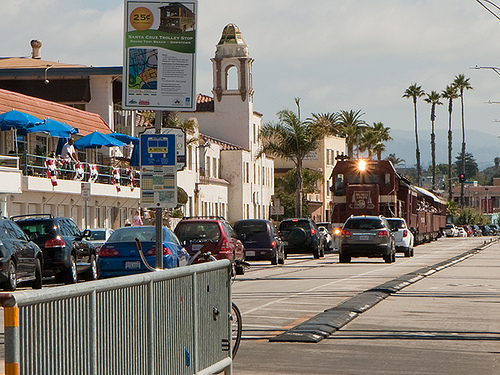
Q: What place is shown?
A: It is a road.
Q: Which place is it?
A: It is a road.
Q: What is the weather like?
A: It is cloudy.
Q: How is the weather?
A: It is cloudy.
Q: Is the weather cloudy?
A: Yes, it is cloudy.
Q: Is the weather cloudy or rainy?
A: It is cloudy.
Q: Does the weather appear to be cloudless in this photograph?
A: No, it is cloudy.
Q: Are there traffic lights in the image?
A: Yes, there is a traffic light.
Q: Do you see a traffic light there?
A: Yes, there is a traffic light.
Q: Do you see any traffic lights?
A: Yes, there is a traffic light.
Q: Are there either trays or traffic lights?
A: Yes, there is a traffic light.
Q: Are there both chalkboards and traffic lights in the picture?
A: No, there is a traffic light but no chalkboards.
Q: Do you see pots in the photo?
A: No, there are no pots.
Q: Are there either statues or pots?
A: No, there are no pots or statues.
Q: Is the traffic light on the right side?
A: Yes, the traffic light is on the right of the image.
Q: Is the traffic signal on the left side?
A: No, the traffic signal is on the right of the image.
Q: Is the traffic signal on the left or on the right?
A: The traffic signal is on the right of the image.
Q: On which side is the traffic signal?
A: The traffic signal is on the right of the image.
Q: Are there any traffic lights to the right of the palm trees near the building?
A: Yes, there is a traffic light to the right of the palm trees.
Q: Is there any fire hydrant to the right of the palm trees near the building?
A: No, there is a traffic light to the right of the palm trees.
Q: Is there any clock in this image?
A: No, there are no clocks.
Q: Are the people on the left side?
A: Yes, the people are on the left of the image.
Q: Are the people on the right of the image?
A: No, the people are on the left of the image.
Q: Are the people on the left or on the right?
A: The people are on the left of the image.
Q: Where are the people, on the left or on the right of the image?
A: The people are on the left of the image.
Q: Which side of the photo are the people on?
A: The people are on the left of the image.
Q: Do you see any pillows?
A: No, there are no pillows.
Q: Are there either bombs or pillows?
A: No, there are no pillows or bombs.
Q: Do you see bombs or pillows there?
A: No, there are no pillows or bombs.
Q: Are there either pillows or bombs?
A: No, there are no pillows or bombs.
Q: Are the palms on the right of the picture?
A: Yes, the palms are on the right of the image.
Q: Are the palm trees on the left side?
A: No, the palm trees are on the right of the image.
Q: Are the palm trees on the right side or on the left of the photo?
A: The palm trees are on the right of the image.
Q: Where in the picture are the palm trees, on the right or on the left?
A: The palm trees are on the right of the image.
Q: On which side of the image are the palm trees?
A: The palm trees are on the right of the image.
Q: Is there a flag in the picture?
A: No, there are no flags.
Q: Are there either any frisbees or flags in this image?
A: No, there are no flags or frisbees.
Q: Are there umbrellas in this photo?
A: Yes, there are umbrellas.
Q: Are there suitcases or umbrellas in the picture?
A: Yes, there are umbrellas.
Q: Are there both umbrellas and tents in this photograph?
A: No, there are umbrellas but no tents.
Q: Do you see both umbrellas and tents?
A: No, there are umbrellas but no tents.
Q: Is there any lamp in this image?
A: No, there are no lamps.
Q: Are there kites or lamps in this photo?
A: No, there are no lamps or kites.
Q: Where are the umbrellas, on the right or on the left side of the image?
A: The umbrellas are on the left of the image.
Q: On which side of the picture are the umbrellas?
A: The umbrellas are on the left of the image.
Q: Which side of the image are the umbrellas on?
A: The umbrellas are on the left of the image.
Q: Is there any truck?
A: No, there are no trucks.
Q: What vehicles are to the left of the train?
A: The vehicles are cars.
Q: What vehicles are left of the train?
A: The vehicles are cars.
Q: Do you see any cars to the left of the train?
A: Yes, there are cars to the left of the train.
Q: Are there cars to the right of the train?
A: No, the cars are to the left of the train.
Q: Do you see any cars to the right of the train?
A: No, the cars are to the left of the train.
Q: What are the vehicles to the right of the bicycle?
A: The vehicles are cars.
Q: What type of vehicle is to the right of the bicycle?
A: The vehicles are cars.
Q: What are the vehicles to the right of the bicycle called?
A: The vehicles are cars.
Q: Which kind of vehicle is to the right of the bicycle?
A: The vehicles are cars.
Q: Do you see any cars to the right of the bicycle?
A: Yes, there are cars to the right of the bicycle.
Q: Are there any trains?
A: Yes, there is a train.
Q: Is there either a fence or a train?
A: Yes, there is a train.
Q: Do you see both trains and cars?
A: Yes, there are both a train and a car.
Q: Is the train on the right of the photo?
A: Yes, the train is on the right of the image.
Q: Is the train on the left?
A: No, the train is on the right of the image.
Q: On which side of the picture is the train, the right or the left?
A: The train is on the right of the image.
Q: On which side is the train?
A: The train is on the right of the image.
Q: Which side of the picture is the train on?
A: The train is on the right of the image.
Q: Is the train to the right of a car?
A: Yes, the train is to the right of a car.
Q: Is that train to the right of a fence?
A: No, the train is to the right of the car.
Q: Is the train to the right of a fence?
A: No, the train is to the right of a car.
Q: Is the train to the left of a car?
A: No, the train is to the right of a car.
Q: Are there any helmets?
A: No, there are no helmets.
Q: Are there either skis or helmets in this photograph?
A: No, there are no helmets or skis.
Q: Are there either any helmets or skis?
A: No, there are no helmets or skis.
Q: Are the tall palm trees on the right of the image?
A: Yes, the palms are on the right of the image.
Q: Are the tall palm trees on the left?
A: No, the palm trees are on the right of the image.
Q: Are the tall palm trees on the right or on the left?
A: The palms are on the right of the image.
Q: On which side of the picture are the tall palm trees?
A: The palm trees are on the right of the image.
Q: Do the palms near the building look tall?
A: Yes, the palm trees are tall.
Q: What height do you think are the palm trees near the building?
A: The palm trees are tall.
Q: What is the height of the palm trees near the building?
A: The palm trees are tall.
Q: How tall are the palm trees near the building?
A: The palm trees are tall.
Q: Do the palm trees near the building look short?
A: No, the palm trees are tall.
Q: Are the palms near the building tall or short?
A: The palms are tall.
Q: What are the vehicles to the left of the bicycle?
A: The vehicles are cars.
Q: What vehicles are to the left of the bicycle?
A: The vehicles are cars.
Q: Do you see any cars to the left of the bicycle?
A: Yes, there are cars to the left of the bicycle.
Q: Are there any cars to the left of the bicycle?
A: Yes, there are cars to the left of the bicycle.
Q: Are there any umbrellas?
A: Yes, there are umbrellas.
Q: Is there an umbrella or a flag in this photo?
A: Yes, there are umbrellas.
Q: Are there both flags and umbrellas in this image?
A: No, there are umbrellas but no flags.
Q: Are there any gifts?
A: No, there are no gifts.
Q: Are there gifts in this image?
A: No, there are no gifts.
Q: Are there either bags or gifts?
A: No, there are no gifts or bags.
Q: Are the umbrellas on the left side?
A: Yes, the umbrellas are on the left of the image.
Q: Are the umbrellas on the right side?
A: No, the umbrellas are on the left of the image.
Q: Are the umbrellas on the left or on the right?
A: The umbrellas are on the left of the image.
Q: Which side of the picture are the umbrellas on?
A: The umbrellas are on the left of the image.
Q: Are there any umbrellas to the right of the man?
A: Yes, there are umbrellas to the right of the man.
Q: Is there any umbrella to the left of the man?
A: No, the umbrellas are to the right of the man.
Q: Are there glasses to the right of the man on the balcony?
A: No, there are umbrellas to the right of the man.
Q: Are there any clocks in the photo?
A: No, there are no clocks.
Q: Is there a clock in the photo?
A: No, there are no clocks.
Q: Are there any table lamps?
A: No, there are no table lamps.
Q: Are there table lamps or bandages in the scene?
A: No, there are no table lamps or bandages.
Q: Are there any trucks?
A: No, there are no trucks.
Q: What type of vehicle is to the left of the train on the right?
A: The vehicle is a car.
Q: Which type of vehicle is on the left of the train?
A: The vehicle is a car.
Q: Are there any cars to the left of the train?
A: Yes, there is a car to the left of the train.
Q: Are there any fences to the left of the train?
A: No, there is a car to the left of the train.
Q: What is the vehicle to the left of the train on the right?
A: The vehicle is a car.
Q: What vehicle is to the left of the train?
A: The vehicle is a car.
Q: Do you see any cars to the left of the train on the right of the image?
A: Yes, there is a car to the left of the train.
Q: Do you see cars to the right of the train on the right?
A: No, the car is to the left of the train.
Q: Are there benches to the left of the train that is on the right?
A: No, there is a car to the left of the train.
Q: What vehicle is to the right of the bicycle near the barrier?
A: The vehicle is a car.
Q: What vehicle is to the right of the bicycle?
A: The vehicle is a car.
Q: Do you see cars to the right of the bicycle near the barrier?
A: Yes, there is a car to the right of the bicycle.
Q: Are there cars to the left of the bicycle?
A: No, the car is to the right of the bicycle.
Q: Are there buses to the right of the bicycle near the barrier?
A: No, there is a car to the right of the bicycle.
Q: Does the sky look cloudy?
A: Yes, the sky is cloudy.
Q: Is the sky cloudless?
A: No, the sky is cloudy.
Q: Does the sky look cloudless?
A: No, the sky is cloudy.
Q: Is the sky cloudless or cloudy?
A: The sky is cloudy.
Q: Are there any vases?
A: No, there are no vases.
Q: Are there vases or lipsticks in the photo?
A: No, there are no vases or lipsticks.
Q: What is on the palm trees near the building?
A: The leaves are on the palm trees.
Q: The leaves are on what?
A: The leaves are on the palms.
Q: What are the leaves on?
A: The leaves are on the palms.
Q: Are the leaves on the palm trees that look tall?
A: Yes, the leaves are on the palms.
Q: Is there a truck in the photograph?
A: No, there are no trucks.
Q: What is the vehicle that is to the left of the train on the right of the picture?
A: The vehicle is a car.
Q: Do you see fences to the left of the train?
A: No, there is a car to the left of the train.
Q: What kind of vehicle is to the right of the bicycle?
A: The vehicle is a car.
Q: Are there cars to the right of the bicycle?
A: Yes, there is a car to the right of the bicycle.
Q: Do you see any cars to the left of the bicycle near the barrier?
A: No, the car is to the right of the bicycle.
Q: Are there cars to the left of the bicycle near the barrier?
A: No, the car is to the right of the bicycle.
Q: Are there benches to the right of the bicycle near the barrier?
A: No, there is a car to the right of the bicycle.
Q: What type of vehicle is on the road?
A: The vehicle is a car.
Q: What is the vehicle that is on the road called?
A: The vehicle is a car.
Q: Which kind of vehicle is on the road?
A: The vehicle is a car.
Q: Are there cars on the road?
A: Yes, there is a car on the road.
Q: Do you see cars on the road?
A: Yes, there is a car on the road.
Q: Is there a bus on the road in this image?
A: No, there is a car on the road.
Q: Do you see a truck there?
A: No, there are no trucks.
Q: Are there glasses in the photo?
A: No, there are no glasses.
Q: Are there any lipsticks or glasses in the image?
A: No, there are no glasses or lipsticks.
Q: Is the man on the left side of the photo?
A: Yes, the man is on the left of the image.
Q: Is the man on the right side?
A: No, the man is on the left of the image.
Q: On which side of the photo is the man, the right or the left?
A: The man is on the left of the image.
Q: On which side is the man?
A: The man is on the left of the image.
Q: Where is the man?
A: The man is on the balcony.